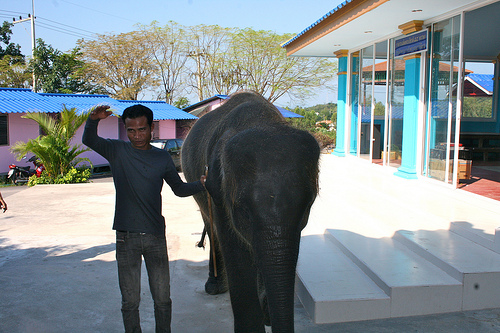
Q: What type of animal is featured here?
A: Elephant.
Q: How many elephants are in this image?
A: One.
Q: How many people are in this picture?
A: One.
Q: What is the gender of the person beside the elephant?
A: Male.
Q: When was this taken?
A: Daytime.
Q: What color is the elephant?
A: Grey.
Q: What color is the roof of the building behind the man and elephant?
A: Blue.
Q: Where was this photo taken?
A: At a house.